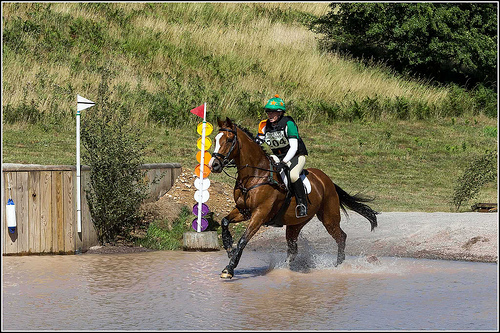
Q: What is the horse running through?
A: Water.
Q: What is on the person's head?
A: A helmet.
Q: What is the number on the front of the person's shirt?
A: 204.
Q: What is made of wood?
A: The fence.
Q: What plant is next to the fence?
A: A bush.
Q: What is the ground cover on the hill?
A: Grass.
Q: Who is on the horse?
A: A man.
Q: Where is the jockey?
A: Riding the horse.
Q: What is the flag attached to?
A: A pole.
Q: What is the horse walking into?
A: Water.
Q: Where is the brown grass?
A: On the hill.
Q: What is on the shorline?
A: Dirt.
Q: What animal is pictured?
A: Horse.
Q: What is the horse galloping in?
A: Water.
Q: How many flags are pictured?
A: Two.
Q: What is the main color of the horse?
A: Brown.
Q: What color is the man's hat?
A: Green.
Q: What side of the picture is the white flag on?
A: Left.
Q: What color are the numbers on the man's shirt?
A: Black.